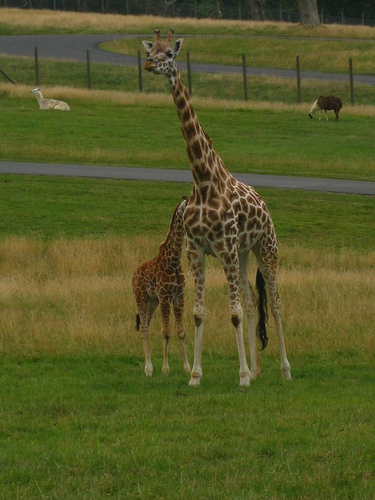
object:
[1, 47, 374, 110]
fence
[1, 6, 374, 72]
grass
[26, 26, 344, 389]
animals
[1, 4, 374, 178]
field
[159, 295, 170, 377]
leg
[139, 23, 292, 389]
adult giraffe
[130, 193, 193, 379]
baby giraffe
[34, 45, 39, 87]
post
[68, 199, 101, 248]
grass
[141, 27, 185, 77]
head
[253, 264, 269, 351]
tail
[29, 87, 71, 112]
llama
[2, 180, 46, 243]
grass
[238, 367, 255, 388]
hoof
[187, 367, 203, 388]
hoof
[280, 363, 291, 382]
hoof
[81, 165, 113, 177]
asphalt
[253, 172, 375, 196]
walkway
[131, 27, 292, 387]
two giraffes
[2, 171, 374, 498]
field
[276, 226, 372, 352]
grass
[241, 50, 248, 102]
post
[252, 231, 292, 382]
leg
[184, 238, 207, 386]
front leg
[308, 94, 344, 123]
llama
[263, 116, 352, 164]
grass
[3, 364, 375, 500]
grass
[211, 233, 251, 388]
front leg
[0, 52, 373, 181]
grass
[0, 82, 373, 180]
grass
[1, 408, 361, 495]
grass